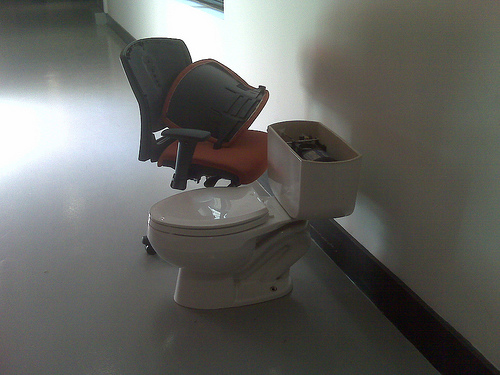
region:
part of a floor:
[110, 318, 145, 353]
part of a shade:
[381, 163, 415, 230]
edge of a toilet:
[184, 186, 246, 274]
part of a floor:
[79, 266, 126, 318]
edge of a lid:
[188, 196, 240, 262]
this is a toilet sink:
[161, 179, 263, 296]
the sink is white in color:
[183, 251, 224, 283]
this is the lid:
[169, 190, 236, 223]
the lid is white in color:
[181, 183, 226, 224]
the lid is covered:
[166, 186, 251, 228]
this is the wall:
[367, 10, 484, 215]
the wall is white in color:
[393, 43, 439, 160]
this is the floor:
[25, 203, 87, 325]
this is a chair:
[115, 34, 238, 171]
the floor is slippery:
[31, 162, 81, 270]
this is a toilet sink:
[156, 184, 276, 303]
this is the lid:
[150, 196, 265, 227]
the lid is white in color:
[175, 183, 242, 198]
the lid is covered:
[148, 204, 238, 221]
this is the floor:
[12, 88, 114, 268]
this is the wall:
[390, 27, 463, 159]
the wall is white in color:
[403, 40, 468, 215]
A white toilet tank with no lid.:
[263, 117, 359, 220]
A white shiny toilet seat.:
[148, 183, 267, 231]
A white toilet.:
[146, 118, 362, 307]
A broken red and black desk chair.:
[118, 38, 271, 253]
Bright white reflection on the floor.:
[3, 91, 71, 183]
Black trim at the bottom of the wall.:
[104, 15, 497, 374]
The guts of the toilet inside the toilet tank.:
[287, 132, 337, 162]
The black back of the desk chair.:
[120, 35, 194, 160]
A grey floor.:
[1, 5, 436, 373]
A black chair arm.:
[159, 125, 211, 143]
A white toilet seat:
[146, 190, 320, 307]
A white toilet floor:
[42, 290, 131, 374]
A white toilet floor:
[133, 304, 282, 370]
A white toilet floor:
[307, 287, 377, 373]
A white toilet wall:
[404, 184, 499, 310]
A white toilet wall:
[404, 62, 497, 159]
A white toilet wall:
[332, 18, 415, 124]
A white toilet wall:
[419, 8, 499, 48]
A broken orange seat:
[101, 28, 273, 190]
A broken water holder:
[256, 110, 370, 214]